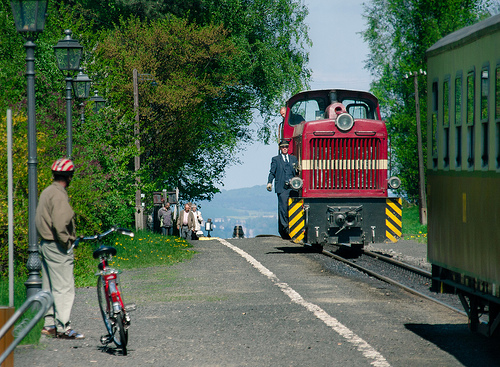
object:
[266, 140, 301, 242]
man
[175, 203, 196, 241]
people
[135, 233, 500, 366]
asphalt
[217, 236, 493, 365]
road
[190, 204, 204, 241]
person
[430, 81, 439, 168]
window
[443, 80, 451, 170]
window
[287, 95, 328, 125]
window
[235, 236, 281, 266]
ground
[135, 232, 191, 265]
grass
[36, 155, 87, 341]
man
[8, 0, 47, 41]
lamp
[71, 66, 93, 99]
lamp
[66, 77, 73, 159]
post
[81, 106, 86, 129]
post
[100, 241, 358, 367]
pavement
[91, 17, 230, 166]
trees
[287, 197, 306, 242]
warning sign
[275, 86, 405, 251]
red train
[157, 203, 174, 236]
people walking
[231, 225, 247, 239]
brown and white car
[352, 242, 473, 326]
tracks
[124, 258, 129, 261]
yellow flowers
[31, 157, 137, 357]
holding a bike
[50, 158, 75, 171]
red and white stripe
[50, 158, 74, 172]
helmet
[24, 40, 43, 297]
metal light post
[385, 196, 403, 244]
caution sign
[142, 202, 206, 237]
group of people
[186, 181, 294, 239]
dark mountain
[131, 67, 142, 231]
grey light pole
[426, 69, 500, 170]
group of windows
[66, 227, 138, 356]
red bicycle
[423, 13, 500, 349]
green train car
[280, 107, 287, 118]
man's head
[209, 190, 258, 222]
behind engine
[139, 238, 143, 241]
flowers dotting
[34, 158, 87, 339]
beside a bicycle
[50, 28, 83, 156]
street lamps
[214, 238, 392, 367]
white line